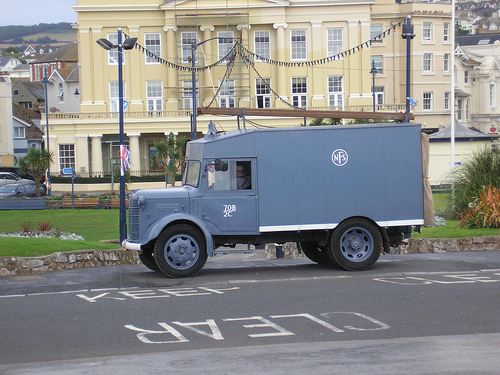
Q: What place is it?
A: It is a pavement.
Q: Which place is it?
A: It is a pavement.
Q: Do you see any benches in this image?
A: Yes, there is a bench.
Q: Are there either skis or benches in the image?
A: Yes, there is a bench.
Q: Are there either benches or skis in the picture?
A: Yes, there is a bench.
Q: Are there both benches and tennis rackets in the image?
A: No, there is a bench but no rackets.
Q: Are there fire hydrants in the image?
A: No, there are no fire hydrants.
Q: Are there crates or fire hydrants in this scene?
A: No, there are no fire hydrants or crates.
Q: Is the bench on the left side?
A: Yes, the bench is on the left of the image.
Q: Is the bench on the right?
A: No, the bench is on the left of the image.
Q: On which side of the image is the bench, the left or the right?
A: The bench is on the left of the image.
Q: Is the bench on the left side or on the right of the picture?
A: The bench is on the left of the image.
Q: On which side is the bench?
A: The bench is on the left of the image.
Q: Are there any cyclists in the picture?
A: No, there are no cyclists.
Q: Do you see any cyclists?
A: No, there are no cyclists.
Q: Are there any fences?
A: No, there are no fences.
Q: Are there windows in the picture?
A: Yes, there is a window.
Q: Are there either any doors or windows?
A: Yes, there is a window.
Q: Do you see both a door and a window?
A: Yes, there are both a window and a door.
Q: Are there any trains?
A: No, there are no trains.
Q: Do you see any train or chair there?
A: No, there are no trains or chairs.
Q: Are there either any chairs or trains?
A: No, there are no trains or chairs.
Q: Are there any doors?
A: Yes, there is a door.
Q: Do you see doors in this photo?
A: Yes, there is a door.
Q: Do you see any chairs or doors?
A: Yes, there is a door.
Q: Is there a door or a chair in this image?
A: Yes, there is a door.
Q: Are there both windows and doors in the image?
A: Yes, there are both a door and windows.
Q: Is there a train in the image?
A: No, there are no trains.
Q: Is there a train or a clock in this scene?
A: No, there are no trains or clocks.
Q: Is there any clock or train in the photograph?
A: No, there are no trains or clocks.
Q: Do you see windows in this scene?
A: Yes, there is a window.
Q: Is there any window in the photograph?
A: Yes, there is a window.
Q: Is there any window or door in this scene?
A: Yes, there is a window.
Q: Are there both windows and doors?
A: Yes, there are both a window and a door.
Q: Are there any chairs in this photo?
A: No, there are no chairs.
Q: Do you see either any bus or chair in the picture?
A: No, there are no chairs or buses.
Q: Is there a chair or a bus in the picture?
A: No, there are no chairs or buses.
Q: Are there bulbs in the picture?
A: No, there are no bulbs.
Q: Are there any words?
A: Yes, there are words.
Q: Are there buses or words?
A: Yes, there are words.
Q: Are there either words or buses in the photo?
A: Yes, there are words.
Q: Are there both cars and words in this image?
A: Yes, there are both words and a car.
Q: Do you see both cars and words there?
A: Yes, there are both words and a car.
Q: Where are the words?
A: The words are on the pavement.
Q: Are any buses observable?
A: No, there are no buses.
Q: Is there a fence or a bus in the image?
A: No, there are no buses or fences.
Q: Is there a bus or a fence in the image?
A: No, there are no buses or fences.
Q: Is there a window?
A: Yes, there is a window.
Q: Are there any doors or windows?
A: Yes, there is a window.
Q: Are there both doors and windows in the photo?
A: Yes, there are both a window and a door.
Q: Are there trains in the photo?
A: No, there are no trains.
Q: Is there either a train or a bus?
A: No, there are no trains or buses.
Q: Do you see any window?
A: Yes, there is a window.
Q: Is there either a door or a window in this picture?
A: Yes, there is a window.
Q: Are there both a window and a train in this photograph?
A: No, there is a window but no trains.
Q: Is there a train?
A: No, there are no trains.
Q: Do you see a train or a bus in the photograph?
A: No, there are no trains or buses.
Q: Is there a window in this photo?
A: Yes, there is a window.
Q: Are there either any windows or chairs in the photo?
A: Yes, there is a window.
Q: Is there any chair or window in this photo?
A: Yes, there is a window.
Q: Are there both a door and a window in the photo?
A: Yes, there are both a window and a door.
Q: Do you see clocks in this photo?
A: No, there are no clocks.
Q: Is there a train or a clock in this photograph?
A: No, there are no clocks or trains.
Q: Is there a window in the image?
A: Yes, there is a window.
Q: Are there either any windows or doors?
A: Yes, there is a window.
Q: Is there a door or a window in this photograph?
A: Yes, there is a window.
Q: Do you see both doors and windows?
A: Yes, there are both a window and a door.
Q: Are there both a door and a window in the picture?
A: Yes, there are both a window and a door.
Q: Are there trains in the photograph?
A: No, there are no trains.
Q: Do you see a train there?
A: No, there are no trains.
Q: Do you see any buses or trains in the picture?
A: No, there are no trains or buses.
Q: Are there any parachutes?
A: No, there are no parachutes.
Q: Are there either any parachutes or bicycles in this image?
A: No, there are no parachutes or bicycles.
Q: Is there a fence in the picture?
A: No, there are no fences.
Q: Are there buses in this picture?
A: No, there are no buses.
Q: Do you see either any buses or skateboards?
A: No, there are no buses or skateboards.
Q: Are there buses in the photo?
A: No, there are no buses.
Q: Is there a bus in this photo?
A: No, there are no buses.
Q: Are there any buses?
A: No, there are no buses.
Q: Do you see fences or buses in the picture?
A: No, there are no buses or fences.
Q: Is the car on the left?
A: Yes, the car is on the left of the image.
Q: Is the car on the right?
A: No, the car is on the left of the image.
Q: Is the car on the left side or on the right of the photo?
A: The car is on the left of the image.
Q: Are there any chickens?
A: No, there are no chickens.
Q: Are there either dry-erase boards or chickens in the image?
A: No, there are no chickens or dry-erase boards.